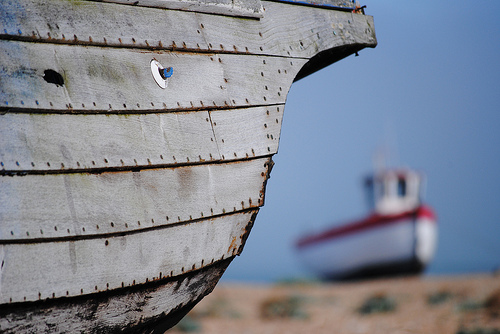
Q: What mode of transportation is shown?
A: Boats.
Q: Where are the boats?
A: On the shore.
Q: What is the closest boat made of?
A: Wood.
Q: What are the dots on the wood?
A: Nails.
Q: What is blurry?
A: Background.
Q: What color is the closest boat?
A: Gray.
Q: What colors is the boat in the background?
A: White and red.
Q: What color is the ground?
A: Tan.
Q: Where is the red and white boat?
A: On a hill.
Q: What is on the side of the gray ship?
A: Small rivets.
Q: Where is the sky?
A: Back ground.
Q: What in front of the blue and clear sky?
A: Top of boat.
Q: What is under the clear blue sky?
A: Red and white boat.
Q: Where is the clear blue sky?
A: Above red and white boat.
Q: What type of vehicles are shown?
A: Boats.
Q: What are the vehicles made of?
A: Wood.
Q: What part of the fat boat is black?
A: Bottom.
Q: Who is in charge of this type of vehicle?
A: Captain.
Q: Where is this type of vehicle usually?
A: Water.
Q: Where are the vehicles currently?
A: Desert.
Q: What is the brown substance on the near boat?
A: Rust.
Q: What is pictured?
A: Side of a boat.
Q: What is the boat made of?
A: Wood and metal.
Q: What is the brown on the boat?
A: Rust.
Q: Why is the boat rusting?
A: It is old.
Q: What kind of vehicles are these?
A: Boats.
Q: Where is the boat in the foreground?
A: On the left.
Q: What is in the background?
A: Red and white boat.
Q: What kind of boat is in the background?
A: Red and white boat.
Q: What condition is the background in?
A: Blurry.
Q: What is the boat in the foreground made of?
A: Wood.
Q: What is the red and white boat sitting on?
A: Sand.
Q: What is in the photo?
A: Boats.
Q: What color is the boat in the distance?
A: White.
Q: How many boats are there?
A: Two.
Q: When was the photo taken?
A: Afternoon.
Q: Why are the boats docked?
A: No water.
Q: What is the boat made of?
A: Wood.